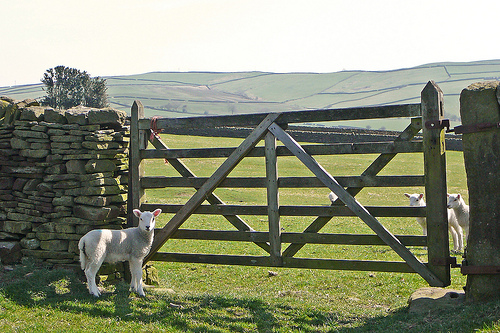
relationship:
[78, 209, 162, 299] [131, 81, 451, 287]
lamb standing outside of gate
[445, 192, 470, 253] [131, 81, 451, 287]
lamb standing inside gate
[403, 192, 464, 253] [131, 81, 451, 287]
lamb standing inside gate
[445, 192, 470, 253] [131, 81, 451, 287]
lamb inside gate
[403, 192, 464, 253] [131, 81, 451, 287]
lamb inside gate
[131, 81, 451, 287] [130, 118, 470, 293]
gate to pasture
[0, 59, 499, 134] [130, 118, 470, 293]
hillside by pasture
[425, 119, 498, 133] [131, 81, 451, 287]
hinge on gate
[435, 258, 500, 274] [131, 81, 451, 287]
hinge on gate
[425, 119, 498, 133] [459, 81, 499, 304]
hinge on wall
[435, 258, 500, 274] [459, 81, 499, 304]
hinge on wall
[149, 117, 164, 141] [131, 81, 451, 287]
cloth on gate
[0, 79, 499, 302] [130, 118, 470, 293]
stone way in front of pasture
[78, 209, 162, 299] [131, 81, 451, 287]
lamb outside of gate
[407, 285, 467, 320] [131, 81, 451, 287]
rock under gate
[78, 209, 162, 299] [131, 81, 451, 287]
lamb standing in front of gate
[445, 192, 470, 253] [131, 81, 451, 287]
lamb standing behind gate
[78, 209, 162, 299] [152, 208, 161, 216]
lamb has a ear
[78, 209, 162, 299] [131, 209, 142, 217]
lamb has a ear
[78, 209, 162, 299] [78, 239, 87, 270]
lamb has a tail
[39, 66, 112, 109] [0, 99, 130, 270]
tree behind wall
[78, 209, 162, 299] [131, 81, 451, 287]
lamb in front of gate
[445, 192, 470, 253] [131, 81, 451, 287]
lamb behind gate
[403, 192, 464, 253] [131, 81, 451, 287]
lamb behind gate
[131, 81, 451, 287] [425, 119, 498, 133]
gate has a hinge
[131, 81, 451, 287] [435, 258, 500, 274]
gate has a hinge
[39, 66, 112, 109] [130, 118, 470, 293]
tree in pasture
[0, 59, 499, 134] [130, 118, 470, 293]
hillside behind pasture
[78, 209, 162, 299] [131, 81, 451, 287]
lamb near gate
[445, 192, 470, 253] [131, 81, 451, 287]
lamb near gate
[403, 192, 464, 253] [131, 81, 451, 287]
lamb near gate